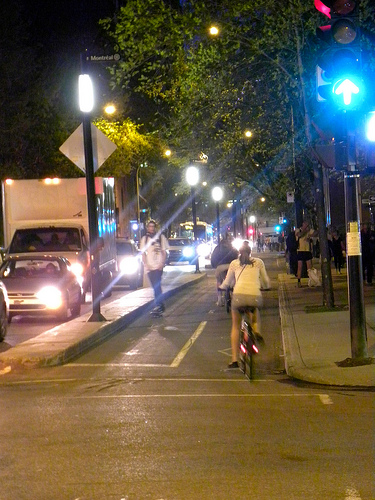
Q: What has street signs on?
A: Tall post.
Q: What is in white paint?
A: The crosswalk.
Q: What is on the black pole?
A: The traffic signal.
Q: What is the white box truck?
A: Large.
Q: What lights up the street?
A: Street lights.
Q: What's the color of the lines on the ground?
A: White.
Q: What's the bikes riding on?
A: Street.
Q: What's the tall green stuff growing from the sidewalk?
A: Trees.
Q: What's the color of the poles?
A: Black.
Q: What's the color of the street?
A: Gray.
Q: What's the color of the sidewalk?
A: Gray.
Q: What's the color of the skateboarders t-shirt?
A: White.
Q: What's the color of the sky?
A: Black.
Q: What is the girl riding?
A: A bike.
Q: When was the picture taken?
A: Night time.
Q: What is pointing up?
A: An arrow.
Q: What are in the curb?
A: Street Lights.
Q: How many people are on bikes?
A: Two.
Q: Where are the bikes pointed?
A: Away.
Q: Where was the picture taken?
A: On the street.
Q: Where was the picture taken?
A: Along the bike path.